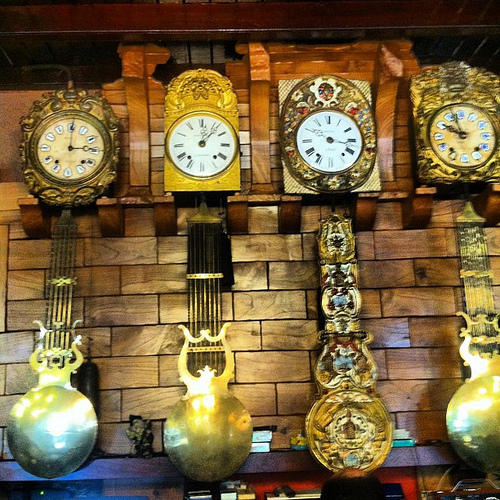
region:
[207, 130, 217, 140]
long arm of a clock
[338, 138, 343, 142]
short hand of a clock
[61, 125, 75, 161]
inside part of a clock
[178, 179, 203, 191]
gold part of a clock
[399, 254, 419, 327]
section of a wooden surface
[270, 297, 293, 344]
part of a brick wall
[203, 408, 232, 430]
brown part of a wall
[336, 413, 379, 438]
images on a clock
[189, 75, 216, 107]
upper part of a clock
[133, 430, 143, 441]
sculpture next to a clock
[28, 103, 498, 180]
Four clock faces on a wall.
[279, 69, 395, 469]
Large decorative clock to the right.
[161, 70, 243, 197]
Gold part of a clock on a wall.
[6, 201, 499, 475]
Four clock pendulums hanging from large clocks.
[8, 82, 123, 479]
Large decorative clock with pendulum on the far left.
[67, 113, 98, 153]
Thin black hands on a clock face to the far left.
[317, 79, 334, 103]
Circle of jewels on a clock to the middle right.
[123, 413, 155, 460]
A little figure of a person on the wall.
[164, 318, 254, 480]
Shiny gold pendulum bottom on the middle left.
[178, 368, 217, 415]
White spot on a pendulum in the left middle.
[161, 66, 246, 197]
yellow gold wall clock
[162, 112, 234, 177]
clock face reading 12:05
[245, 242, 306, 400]
brick wall behind clocks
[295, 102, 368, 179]
clock face reading 10:18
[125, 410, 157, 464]
small gnome sculpture on shelf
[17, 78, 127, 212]
clock face reading 3:00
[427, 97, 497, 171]
clock face reading 9:56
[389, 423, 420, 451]
books on shelf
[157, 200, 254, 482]
long gold clock pendulum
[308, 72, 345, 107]
colorful gem stones on base of clock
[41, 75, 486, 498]
different types of clocks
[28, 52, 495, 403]
golden clocks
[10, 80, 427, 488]
three clocks are available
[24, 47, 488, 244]
different styles of clocks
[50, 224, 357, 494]
brassy toned bottoms of clocks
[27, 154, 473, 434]
wooden blocks that look like brick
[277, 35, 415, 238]
a colorful clock with a white face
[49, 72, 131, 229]
a golden clock with a yellow face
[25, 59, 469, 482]
four clocks on display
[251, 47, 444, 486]
an ornate clock on display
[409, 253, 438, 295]
black spot on wall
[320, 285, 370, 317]
brown and blue decoration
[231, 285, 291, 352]
gold tiles on the wall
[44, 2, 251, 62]
brown wood on top of clock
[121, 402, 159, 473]
small black and gold figurine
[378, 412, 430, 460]
white and blue paper on mantle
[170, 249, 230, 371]
gold strings on guitar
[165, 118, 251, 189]
roman numerals on clock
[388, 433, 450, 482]
purple counter below guitars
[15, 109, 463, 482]
large selection of colorful guitars